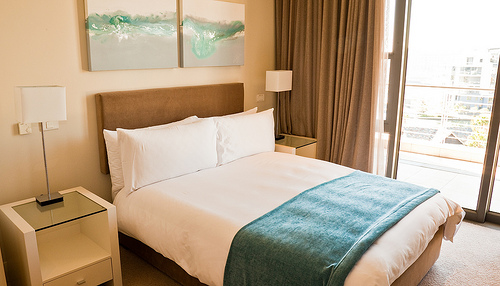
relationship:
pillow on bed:
[117, 119, 218, 193] [97, 83, 466, 285]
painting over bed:
[85, 0, 180, 69] [97, 83, 466, 285]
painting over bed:
[180, 0, 247, 67] [97, 83, 466, 285]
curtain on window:
[275, 1, 385, 173] [373, 1, 499, 223]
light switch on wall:
[18, 124, 33, 135] [0, 1, 277, 206]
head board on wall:
[96, 83, 258, 173] [0, 1, 277, 206]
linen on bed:
[113, 151, 466, 285] [97, 83, 466, 285]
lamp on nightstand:
[19, 87, 70, 206] [0, 186, 123, 285]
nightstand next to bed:
[0, 186, 123, 285] [97, 83, 466, 285]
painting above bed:
[85, 0, 180, 69] [97, 83, 466, 285]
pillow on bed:
[216, 108, 276, 164] [97, 83, 466, 285]